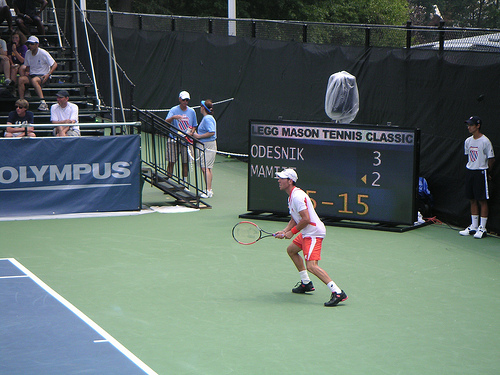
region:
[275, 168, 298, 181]
Man wearing a white hat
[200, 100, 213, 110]
Woman wearing a blue visor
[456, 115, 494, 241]
Man standing against a wall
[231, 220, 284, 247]
Man holding a tennis racket in both hands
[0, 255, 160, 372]
Blue tennis court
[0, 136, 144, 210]
OLYMPUS sign on the stands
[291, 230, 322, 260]
Man wearing red shorts with a white stripe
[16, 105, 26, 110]
Man wearing sun glasses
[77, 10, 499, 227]
Fence behind a tennis court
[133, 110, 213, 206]
Stairs leading to the stands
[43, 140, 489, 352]
scene is at a tennnis playfield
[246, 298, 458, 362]
the floor is rough green in color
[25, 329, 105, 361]
the floor is blue in color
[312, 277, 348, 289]
the socks are white in color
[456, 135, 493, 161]
the shirt is white in color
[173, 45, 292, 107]
the tent is black in color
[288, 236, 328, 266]
the short is red in color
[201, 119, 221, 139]
the blouse is light blue in color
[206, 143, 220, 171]
the shortt is white in color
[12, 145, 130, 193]
wors are written in white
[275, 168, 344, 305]
this is a man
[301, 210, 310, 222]
the elbow is bent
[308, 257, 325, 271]
the man is light skinned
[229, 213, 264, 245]
this is a racket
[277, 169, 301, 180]
this is a cap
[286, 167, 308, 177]
the cap is white in color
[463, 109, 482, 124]
the cap is black in color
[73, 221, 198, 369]
this is the playing ground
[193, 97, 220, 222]
this is a lady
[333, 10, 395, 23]
this is a tree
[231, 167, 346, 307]
the man playing tennis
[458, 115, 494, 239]
the man standing against the fence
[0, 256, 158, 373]
the white lines on the court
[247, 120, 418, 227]
the digital score board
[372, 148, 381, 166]
the number 3 on the score board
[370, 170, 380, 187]
the number 2 on the score board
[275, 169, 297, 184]
the hat on the man's head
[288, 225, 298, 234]
the wristband on the man's arm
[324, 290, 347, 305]
the shoe on the man's foot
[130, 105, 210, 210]
the set of stairs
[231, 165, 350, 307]
Man in shorts playing tennis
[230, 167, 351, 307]
Man in white cap playing tennis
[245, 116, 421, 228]
Black and White tennis score board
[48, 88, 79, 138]
Man in black cap watching tennis match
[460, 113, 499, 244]
Man in black shorts watching tennis match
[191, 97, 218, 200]
Lady in light blue shirt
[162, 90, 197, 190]
Man wearing light blue shirt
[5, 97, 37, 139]
Man wearing sun shades at tennis match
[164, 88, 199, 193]
Man wearing white cap at tennis match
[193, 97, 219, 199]
Lady wearing khaki shorts at tennis match